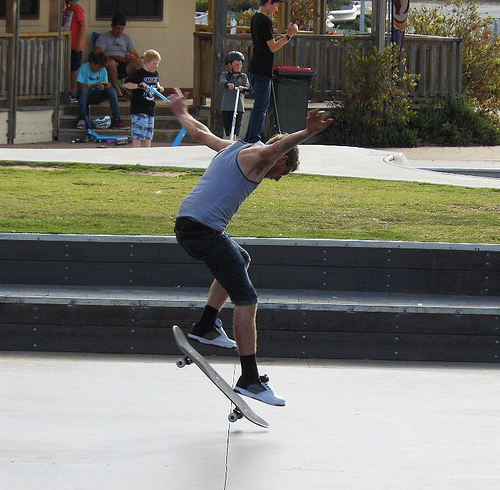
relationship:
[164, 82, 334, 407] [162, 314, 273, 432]
person on skateboard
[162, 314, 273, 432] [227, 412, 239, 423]
skateboard has wheel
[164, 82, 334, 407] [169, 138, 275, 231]
person wearing tank top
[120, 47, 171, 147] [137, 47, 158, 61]
child with hair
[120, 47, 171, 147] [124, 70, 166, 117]
child wearing shirt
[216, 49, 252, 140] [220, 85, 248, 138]
boy with scooter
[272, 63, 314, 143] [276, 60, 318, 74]
garbage can with lid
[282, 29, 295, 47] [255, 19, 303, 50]
watch on arm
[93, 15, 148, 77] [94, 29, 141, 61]
man in shirt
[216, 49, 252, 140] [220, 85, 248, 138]
boy riding scooter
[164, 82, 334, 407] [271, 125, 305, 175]
person has hair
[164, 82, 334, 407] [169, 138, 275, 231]
person wears tank top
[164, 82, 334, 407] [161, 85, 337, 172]
person has arms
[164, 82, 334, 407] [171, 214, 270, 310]
person has shorts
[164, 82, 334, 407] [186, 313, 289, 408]
person has shoes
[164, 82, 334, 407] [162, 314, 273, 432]
person has skateboard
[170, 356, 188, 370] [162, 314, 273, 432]
wheels on skateboard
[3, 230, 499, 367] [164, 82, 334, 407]
wall behind person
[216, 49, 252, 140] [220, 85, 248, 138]
boy holding scooter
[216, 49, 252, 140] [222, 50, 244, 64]
boy wearing helmet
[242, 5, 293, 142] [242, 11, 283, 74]
man wearing shirt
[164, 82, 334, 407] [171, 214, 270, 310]
person wearing shorts